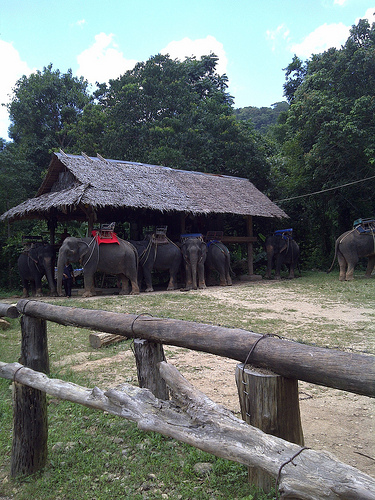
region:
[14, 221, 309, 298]
six elephants standing together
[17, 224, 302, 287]
elephants with seats on them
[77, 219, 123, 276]
a red blanket on a elephant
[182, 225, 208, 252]
a blue blanket on a elephant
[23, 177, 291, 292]
elephants standing under a pavilion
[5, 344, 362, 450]
a tree trunk used as a fence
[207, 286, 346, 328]
patches of grass and sand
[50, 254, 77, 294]
a person standing beside a elephant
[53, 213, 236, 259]
elephants with blankets and seats on their backs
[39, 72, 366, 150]
several tall green trees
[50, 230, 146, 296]
the elephant is gray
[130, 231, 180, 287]
the elephant is gray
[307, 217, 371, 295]
the elephant is gray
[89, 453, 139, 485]
pebbles on the ground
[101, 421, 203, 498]
pebbles on the ground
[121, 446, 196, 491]
pebbles on the ground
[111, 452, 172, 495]
pebbles on the ground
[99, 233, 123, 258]
the blanket is sitting on the elephant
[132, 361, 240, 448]
the log is weathered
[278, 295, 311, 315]
the dirt is tan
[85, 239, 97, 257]
the rope is around the elepahnt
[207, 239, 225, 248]
the blanket is blue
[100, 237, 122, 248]
the blanket is red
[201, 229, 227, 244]
the bench is brown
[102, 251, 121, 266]
the elepjant is light gray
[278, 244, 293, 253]
the elephant is dark gray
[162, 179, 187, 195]
the roof is made of dead hay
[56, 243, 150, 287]
an elephant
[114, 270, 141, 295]
the elephants legs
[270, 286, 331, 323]
dirt in the grass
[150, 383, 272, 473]
a tree log on the ground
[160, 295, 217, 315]
pactches of green grass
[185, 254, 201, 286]
an elephants trunk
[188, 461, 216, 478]
a rock in the grass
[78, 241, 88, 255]
the elephants ear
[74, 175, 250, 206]
the roof of the barn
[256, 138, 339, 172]
the bushes are green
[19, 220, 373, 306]
a herd of elephants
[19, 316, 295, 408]
a wooden pole fence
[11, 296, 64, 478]
a tree stump for a post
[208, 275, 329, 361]
dirt and grass on the ground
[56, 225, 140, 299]
elephant with a red seat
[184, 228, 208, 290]
elephant with blue seat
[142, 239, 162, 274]
elephant with straps under it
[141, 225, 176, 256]
elephant with a brown seat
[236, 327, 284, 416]
wire on the post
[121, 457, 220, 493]
small rocks in the grass